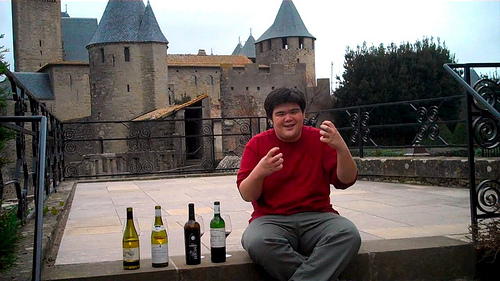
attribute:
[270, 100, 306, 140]
face — smiling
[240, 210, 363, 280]
pants — grey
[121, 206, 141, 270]
bottle — wine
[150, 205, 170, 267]
bottle — wine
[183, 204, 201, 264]
bottle — wine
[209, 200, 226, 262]
bottle — wine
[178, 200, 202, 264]
bottle — glass